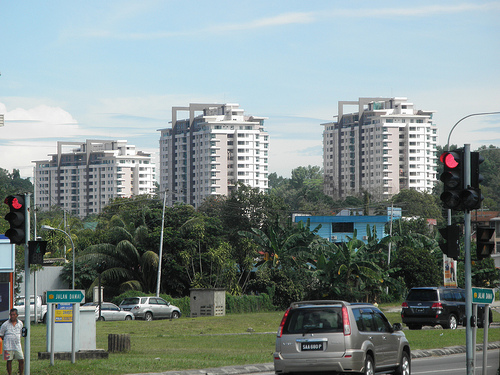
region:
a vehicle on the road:
[274, 297, 409, 374]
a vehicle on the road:
[398, 280, 482, 327]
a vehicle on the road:
[122, 292, 182, 322]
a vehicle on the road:
[82, 295, 126, 329]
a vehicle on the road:
[10, 290, 56, 324]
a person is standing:
[1, 307, 31, 372]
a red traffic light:
[442, 152, 459, 167]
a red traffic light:
[8, 193, 26, 211]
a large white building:
[151, 96, 276, 213]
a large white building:
[302, 91, 441, 208]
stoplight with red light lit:
[422, 127, 487, 239]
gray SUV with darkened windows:
[262, 293, 425, 371]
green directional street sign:
[37, 281, 119, 313]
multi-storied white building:
[142, 97, 287, 207]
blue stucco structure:
[282, 201, 404, 236]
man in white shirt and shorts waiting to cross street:
[0, 307, 40, 371]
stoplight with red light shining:
[1, 191, 38, 276]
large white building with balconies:
[24, 125, 150, 221]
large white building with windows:
[311, 90, 450, 196]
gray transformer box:
[187, 277, 237, 324]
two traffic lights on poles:
[0, 131, 489, 272]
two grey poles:
[3, 136, 477, 372]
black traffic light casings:
[0, 140, 492, 274]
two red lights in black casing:
[5, 143, 471, 243]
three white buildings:
[14, 69, 461, 283]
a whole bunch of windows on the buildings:
[11, 96, 435, 276]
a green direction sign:
[39, 280, 91, 322]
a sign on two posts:
[37, 286, 88, 368]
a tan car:
[255, 275, 430, 374]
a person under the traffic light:
[0, 297, 38, 371]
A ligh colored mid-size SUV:
[270, 301, 415, 371]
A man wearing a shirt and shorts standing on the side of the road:
[1, 305, 28, 370]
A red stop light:
[435, 150, 486, 206]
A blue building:
[285, 205, 390, 251]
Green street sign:
[40, 285, 86, 305]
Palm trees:
[226, 225, 406, 297]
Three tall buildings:
[15, 71, 435, 211]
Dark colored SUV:
[401, 281, 491, 331]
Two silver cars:
[92, 295, 174, 317]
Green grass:
[140, 320, 265, 365]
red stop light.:
[438, 140, 486, 205]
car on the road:
[262, 290, 409, 374]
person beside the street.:
[6, 303, 34, 362]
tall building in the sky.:
[149, 103, 276, 198]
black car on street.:
[396, 281, 488, 326]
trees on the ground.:
[185, 195, 390, 296]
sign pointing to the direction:
[40, 281, 90, 303]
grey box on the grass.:
[186, 285, 241, 320]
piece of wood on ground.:
[105, 326, 146, 346]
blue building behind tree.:
[287, 205, 413, 265]